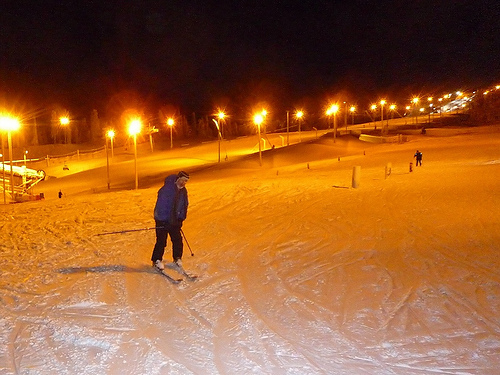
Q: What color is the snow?
A: White.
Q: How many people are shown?
A: Two.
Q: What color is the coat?
A: Blue.